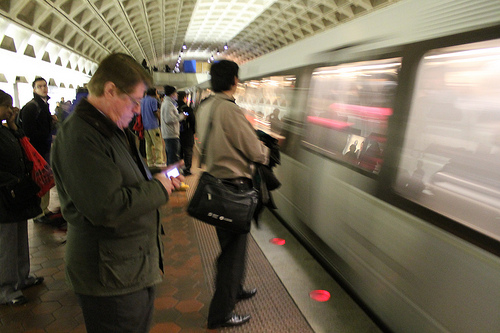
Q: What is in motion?
A: The moving train is in motion.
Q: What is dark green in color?
A: The rain jacket is dark green.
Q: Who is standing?
A: A person is standing.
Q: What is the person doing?
A: The person is standing.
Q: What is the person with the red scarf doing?
A: The person with the red scarf is standing.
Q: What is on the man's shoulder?
A: There is a shoulder bag on the man's shoulder.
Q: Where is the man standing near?
A: The man is standing near a train.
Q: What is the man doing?
A: The man is looking at his cell phone.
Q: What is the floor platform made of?
A: The floor platform is made of tile.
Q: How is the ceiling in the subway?
A: The ceiling is coffered.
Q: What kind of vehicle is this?
A: Train.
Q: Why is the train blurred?
A: Motion.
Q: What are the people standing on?
A: Train platform.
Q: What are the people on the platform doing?
A: Waiting on the train.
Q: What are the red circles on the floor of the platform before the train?
A: Warning lights.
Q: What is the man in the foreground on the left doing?
A: Looking at cell phone.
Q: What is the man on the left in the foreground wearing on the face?
A: Eye glasses.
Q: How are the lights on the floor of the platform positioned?
A: Side by side.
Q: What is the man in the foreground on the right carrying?
A: Black shoulder bag.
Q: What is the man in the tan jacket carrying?
A: A black bag.